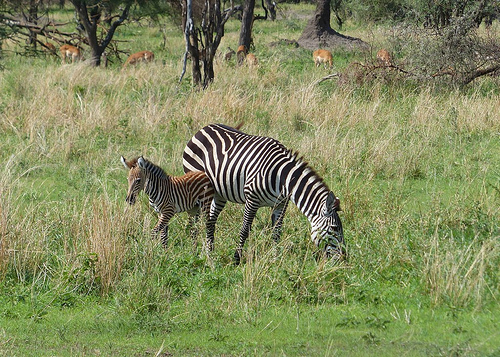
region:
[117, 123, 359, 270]
Two zebra's graze in the grass.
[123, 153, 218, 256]
A baby zebra who has not turned black and white yet.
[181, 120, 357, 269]
The mom zebra grazes.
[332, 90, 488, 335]
Tall grass acts as food.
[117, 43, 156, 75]
Another animal grazes in the back.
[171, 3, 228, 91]
A run down tree.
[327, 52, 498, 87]
A fallen branch acts as protection.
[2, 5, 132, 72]
Fallen trees act as coverage.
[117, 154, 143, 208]
The baby zebra looks on.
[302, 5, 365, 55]
A large tree stump.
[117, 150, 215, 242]
baby zebra in tall grass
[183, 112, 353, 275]
zebra grazing in grass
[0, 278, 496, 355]
short grass in foreground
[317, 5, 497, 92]
leafless bush in background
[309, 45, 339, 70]
antelope grazing in background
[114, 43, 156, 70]
antelope grazing near tree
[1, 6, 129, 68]
fallen tree in background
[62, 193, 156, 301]
tall grass shoots next to baby zebra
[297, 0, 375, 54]
warped tree trunk next to antelope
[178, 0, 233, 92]
leafless trees in center of background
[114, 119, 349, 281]
An adult and baby zebra eating grass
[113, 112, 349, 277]
An adult and baby zebra eating grass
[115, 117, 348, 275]
An adult and baby zebra eating grass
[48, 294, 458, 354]
The grass is short and green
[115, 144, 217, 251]
The baby zebra in the grass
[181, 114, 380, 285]
The large zebra is eating grass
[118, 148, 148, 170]
The ears of the baby zebra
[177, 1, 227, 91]
The tree trunk is the color brown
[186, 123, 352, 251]
The zebra is the color black and white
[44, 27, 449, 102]
The animals eating grass in the land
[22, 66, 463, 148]
The grass is tall and yellow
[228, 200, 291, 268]
The legs on the zebra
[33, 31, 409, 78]
Gazelles on the grass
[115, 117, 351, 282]
Two zebras on the grass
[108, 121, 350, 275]
Small zebra and adult zebra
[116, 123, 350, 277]
Zebra next to younger zebra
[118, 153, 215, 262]
Small zebra on grass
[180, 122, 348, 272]
Adult zebra on the grass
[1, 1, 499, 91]
Trees and bushes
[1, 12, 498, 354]
A green grassy landscape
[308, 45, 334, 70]
A gazelle on the grass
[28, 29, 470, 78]
A group of tan gazelles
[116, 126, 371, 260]
a pair of zebras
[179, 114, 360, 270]
the zebras has stripes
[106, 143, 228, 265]
a small baby giraffe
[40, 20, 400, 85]
a group of gazelles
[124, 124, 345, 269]
An adult zebra with its child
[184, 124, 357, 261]
The healthy mother giraffe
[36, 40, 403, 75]
The grazing impalas in the background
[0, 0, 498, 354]
A grazing land in the wild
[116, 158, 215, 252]
The young zebra in the wild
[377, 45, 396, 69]
The impala on the extreme right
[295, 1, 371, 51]
The large gray tree trunk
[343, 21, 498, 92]
The drying bushes on the right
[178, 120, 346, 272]
a zebra is grazing on the grass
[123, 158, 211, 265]
a little zebra is taking a step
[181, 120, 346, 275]
the zebra is an adult animal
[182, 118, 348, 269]
the zebra has a linear pattern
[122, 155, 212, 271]
the zebra is brownish in color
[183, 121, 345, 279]
the zebra is black and white in color